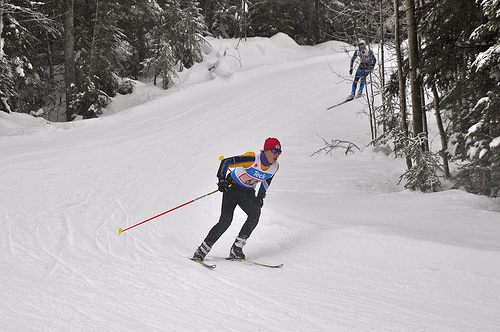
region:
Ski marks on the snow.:
[30, 166, 121, 301]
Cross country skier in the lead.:
[110, 125, 295, 287]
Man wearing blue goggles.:
[262, 132, 288, 159]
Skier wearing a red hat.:
[254, 133, 293, 165]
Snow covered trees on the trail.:
[77, 3, 197, 97]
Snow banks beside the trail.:
[190, 26, 325, 80]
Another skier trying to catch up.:
[321, 20, 388, 128]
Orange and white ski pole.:
[110, 173, 230, 243]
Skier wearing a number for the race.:
[216, 128, 294, 195]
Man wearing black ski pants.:
[180, 184, 267, 264]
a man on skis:
[194, 129, 326, 274]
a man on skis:
[161, 75, 363, 270]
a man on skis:
[170, 172, 300, 310]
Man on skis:
[179, 238, 287, 279]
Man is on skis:
[180, 245, 292, 277]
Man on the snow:
[111, 135, 311, 276]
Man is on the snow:
[117, 131, 302, 268]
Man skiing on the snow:
[115, 127, 295, 272]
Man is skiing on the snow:
[111, 132, 287, 270]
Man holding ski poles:
[106, 151, 271, 245]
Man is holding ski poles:
[113, 150, 263, 235]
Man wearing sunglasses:
[263, 145, 284, 156]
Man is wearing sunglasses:
[259, 145, 286, 155]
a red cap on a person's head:
[262, 137, 280, 151]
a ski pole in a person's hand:
[117, 186, 219, 233]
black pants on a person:
[212, 183, 259, 244]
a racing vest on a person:
[236, 152, 279, 185]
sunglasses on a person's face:
[270, 144, 283, 154]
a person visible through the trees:
[326, 33, 378, 113]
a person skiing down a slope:
[185, 134, 292, 271]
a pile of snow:
[194, 25, 301, 77]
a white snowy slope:
[0, 47, 494, 330]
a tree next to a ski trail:
[58, 0, 86, 122]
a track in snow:
[59, 199, 93, 258]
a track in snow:
[124, 242, 164, 264]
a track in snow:
[153, 233, 175, 264]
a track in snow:
[129, 237, 173, 282]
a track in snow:
[29, 290, 83, 321]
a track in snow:
[9, 227, 37, 261]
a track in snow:
[17, 198, 41, 235]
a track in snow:
[78, 165, 107, 239]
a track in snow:
[122, 165, 167, 226]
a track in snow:
[177, 130, 197, 192]